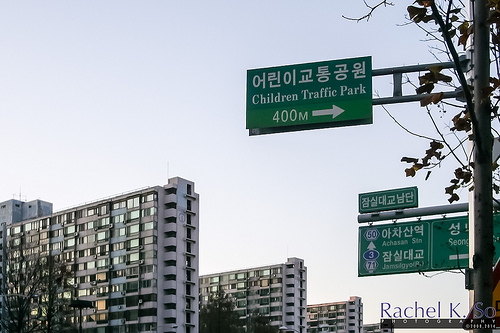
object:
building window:
[124, 247, 141, 263]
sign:
[240, 51, 377, 144]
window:
[147, 207, 155, 216]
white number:
[268, 106, 300, 131]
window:
[210, 278, 219, 284]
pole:
[370, 88, 473, 104]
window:
[87, 209, 95, 218]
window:
[95, 257, 107, 266]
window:
[128, 224, 139, 234]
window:
[130, 224, 140, 233]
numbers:
[367, 231, 376, 239]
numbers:
[368, 252, 375, 259]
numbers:
[368, 261, 378, 268]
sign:
[357, 221, 429, 273]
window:
[64, 224, 75, 234]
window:
[112, 200, 126, 209]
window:
[128, 240, 139, 247]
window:
[111, 200, 125, 209]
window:
[209, 277, 219, 284]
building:
[198, 258, 309, 331]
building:
[304, 296, 364, 332]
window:
[125, 282, 140, 290]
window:
[259, 269, 270, 275]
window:
[329, 313, 335, 317]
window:
[98, 217, 109, 225]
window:
[144, 193, 156, 203]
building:
[0, 163, 244, 333]